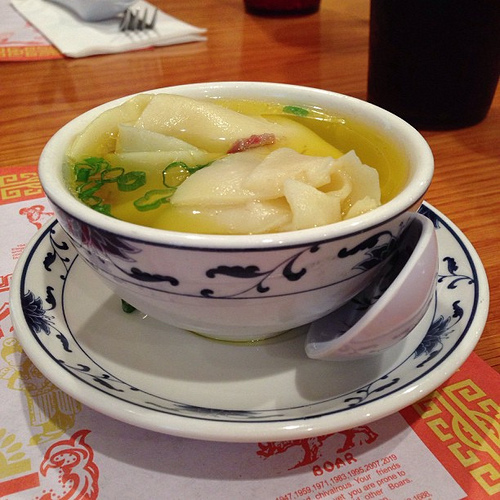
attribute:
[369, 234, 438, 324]
bowl — white, blue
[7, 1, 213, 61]
napkin — paper, white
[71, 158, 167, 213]
green onions — sliced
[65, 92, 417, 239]
soup — yellow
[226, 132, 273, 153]
meat — bit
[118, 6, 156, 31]
fork — stainless steel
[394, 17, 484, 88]
glass — beverage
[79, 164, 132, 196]
onions — green